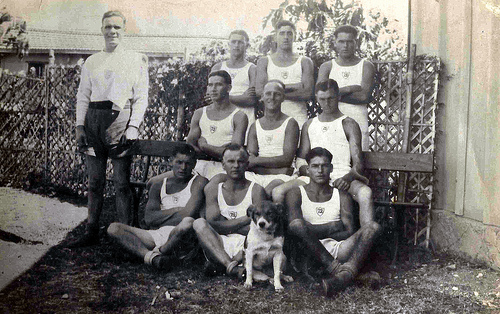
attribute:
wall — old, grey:
[407, 2, 498, 264]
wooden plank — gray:
[113, 134, 433, 181]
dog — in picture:
[241, 200, 296, 295]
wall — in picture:
[407, 0, 499, 232]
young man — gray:
[246, 78, 300, 174]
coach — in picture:
[65, 4, 145, 252]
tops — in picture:
[161, 170, 262, 250]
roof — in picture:
[15, 14, 223, 61]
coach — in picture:
[72, 9, 149, 245]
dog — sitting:
[215, 196, 305, 311]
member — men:
[298, 153, 340, 217]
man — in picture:
[285, 138, 382, 286]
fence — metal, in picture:
[5, 49, 446, 250]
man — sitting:
[81, 7, 156, 254]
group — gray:
[68, 8, 431, 301]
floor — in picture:
[243, 134, 376, 164]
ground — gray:
[407, 246, 466, 292]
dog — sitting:
[237, 199, 306, 293]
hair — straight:
[83, 4, 138, 21]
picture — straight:
[1, 2, 497, 312]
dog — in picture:
[244, 199, 291, 289]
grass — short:
[28, 232, 493, 312]